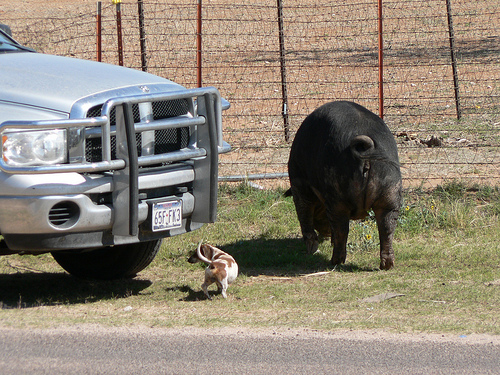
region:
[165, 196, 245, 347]
a dog near truck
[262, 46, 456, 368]
a black animal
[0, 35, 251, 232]
a gray truck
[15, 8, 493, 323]
a scene during the day time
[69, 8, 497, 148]
a wire fence in the background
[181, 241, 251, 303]
The dog in front the truck.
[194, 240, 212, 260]
The tail of the dog.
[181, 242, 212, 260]
The face of the dog.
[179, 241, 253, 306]
The dog has black and white spots.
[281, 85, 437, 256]
The black pig in front the truck.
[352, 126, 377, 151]
The small tail on the pig.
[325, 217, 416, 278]
The back legs of the pig..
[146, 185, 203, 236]
The license plate on the truck.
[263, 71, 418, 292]
this is a pig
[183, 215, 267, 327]
this is a dog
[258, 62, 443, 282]
the pig is black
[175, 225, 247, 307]
the dog is white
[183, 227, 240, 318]
the dog has brown spots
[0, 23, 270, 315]
this is a truck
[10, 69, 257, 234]
grill guard on truck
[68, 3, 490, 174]
a fence in background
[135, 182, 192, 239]
a texas license plate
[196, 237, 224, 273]
dog has tail up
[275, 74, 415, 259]
an animal walking outside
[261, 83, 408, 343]
an animal walking on grass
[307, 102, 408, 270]
a black animal walking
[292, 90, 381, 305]
a black animal walking on grass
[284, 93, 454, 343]
a black animal walking outside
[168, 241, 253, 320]
a dog walking outside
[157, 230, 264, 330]
a small dog walking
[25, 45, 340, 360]
a silver pick up truck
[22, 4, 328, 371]
a truck that is parked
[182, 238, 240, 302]
small dog checking out the car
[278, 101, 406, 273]
large hog eating grass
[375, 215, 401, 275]
large hog has a stubby leg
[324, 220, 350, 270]
large hog has a stubby leg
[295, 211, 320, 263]
large hog has a stubby leg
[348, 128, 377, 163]
large hog has a curly tail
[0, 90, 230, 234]
front grill of pickup is silver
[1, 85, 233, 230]
front grill of pickup is metal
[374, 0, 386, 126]
metal post holding up fence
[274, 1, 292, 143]
metal post holding up fence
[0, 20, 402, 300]
animals next to truck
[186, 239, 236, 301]
dog is white and brown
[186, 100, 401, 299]
small dog next to pig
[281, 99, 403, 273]
pig is big and black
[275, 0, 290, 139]
fence has a post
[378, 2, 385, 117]
fence has a post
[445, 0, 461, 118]
fence has a post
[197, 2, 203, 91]
fence has a post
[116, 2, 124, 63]
fence has a post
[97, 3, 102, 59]
fence has a post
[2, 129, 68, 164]
truck has a headlight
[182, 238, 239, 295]
a small dog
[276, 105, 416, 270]
an animal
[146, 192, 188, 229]
license plate on the truck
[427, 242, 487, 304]
the grass is patchy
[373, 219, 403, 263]
the animals back leg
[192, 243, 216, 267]
the dogs tail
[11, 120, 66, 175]
a clear headlight